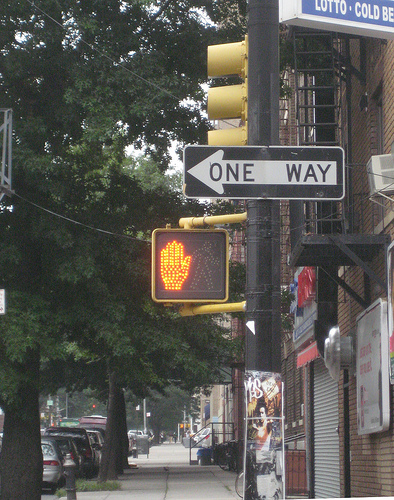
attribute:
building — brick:
[339, 61, 371, 160]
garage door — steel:
[282, 318, 343, 499]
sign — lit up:
[150, 227, 238, 304]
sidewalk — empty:
[128, 440, 218, 494]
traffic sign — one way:
[182, 146, 345, 198]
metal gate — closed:
[313, 353, 338, 498]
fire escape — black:
[289, 34, 367, 295]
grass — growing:
[79, 478, 91, 493]